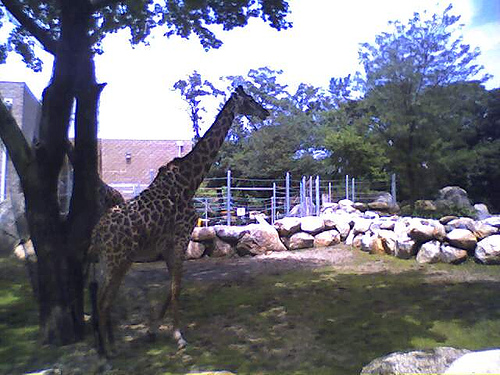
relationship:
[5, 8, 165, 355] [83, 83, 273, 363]
tree next to giraffe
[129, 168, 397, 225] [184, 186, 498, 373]
fence behind rocks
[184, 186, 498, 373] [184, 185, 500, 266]
rocks are in a rocks